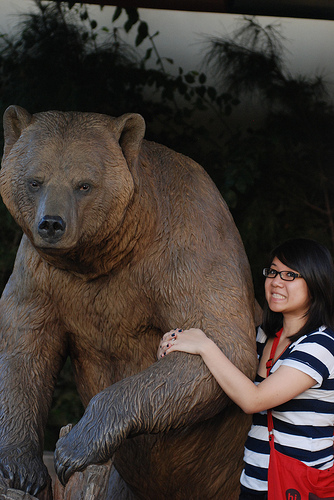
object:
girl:
[149, 242, 333, 495]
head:
[263, 244, 322, 317]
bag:
[264, 439, 331, 499]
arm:
[157, 329, 318, 414]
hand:
[157, 328, 202, 359]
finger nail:
[168, 330, 180, 338]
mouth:
[268, 290, 293, 300]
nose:
[266, 280, 282, 289]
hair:
[261, 224, 329, 342]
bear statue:
[0, 99, 265, 497]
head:
[3, 104, 148, 264]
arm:
[54, 322, 260, 480]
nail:
[170, 328, 188, 333]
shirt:
[235, 329, 333, 499]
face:
[263, 257, 314, 312]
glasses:
[259, 266, 321, 284]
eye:
[74, 178, 98, 194]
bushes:
[188, 1, 295, 159]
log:
[0, 453, 140, 500]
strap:
[266, 319, 276, 450]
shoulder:
[285, 326, 332, 396]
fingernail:
[154, 343, 165, 350]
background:
[0, 4, 333, 499]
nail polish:
[156, 343, 171, 360]